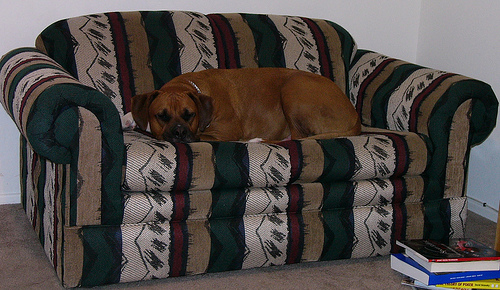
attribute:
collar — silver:
[187, 79, 203, 94]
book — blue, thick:
[380, 250, 492, 288]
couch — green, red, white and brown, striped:
[0, 10, 499, 289]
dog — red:
[125, 66, 369, 152]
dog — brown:
[130, 21, 389, 172]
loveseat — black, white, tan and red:
[2, 8, 496, 289]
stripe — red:
[169, 139, 191, 278]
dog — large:
[127, 72, 361, 140]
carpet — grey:
[327, 254, 392, 288]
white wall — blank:
[385, 10, 473, 45]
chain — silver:
[188, 80, 205, 96]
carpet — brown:
[4, 184, 494, 289]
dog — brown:
[132, 69, 361, 145]